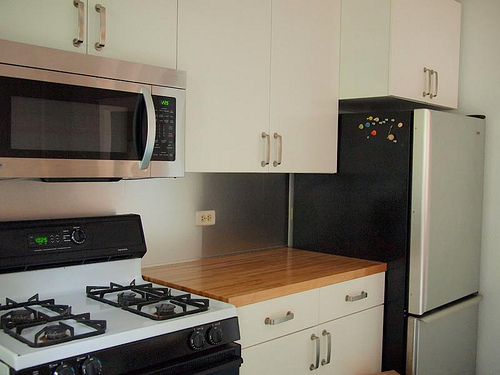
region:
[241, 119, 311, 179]
handles on a kitchen cabinet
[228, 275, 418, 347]
kitchen drawers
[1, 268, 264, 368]
gas stove top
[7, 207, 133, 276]
clock on a stove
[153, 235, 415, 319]
butcher block counter top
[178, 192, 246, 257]
electrical outlet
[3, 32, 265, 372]
microwave over a stove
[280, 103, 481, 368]
refrigerator with black sides and a stainless steel front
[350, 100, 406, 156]
magnets on the side of a refrigerator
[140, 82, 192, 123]
clock on microwave oven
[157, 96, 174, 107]
the numbers are lit up green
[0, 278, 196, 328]
the range is gas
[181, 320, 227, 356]
the knobs are black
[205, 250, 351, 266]
the counter is wooden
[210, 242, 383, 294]
the counter is brown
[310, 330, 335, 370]
the handles are metal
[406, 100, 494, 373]
the fridge is stainless steal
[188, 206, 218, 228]
the socket is on the wall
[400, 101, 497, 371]
the fridge is huge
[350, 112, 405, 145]
the magnets are on the fridge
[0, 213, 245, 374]
a black and white stove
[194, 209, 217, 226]
an electrical wall outlet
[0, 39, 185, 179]
a black and silver microwave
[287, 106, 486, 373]
a black and silver refrigerator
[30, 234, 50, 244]
a clock on a stove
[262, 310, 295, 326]
silver handle on drawer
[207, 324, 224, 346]
black knob on stove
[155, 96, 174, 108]
clock on a microwave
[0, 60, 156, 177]
silver door of microwave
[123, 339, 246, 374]
black door of stove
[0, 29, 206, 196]
microwave over the stove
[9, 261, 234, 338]
four burners on the stove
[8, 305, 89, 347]
the stove is gas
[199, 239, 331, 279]
counter top is wood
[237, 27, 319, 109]
cabinets are white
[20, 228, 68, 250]
clock on the stove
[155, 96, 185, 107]
clock on the microwave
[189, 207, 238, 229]
power outlet on the wall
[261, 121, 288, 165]
silver handles on the cabinets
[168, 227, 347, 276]
counter top is empty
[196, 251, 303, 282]
new brown wood counter top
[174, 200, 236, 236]
white electrical outlet on the wall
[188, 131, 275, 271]
cupboard lines cast on the surface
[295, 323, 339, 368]
silver doors on cabinet front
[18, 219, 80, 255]
green light on stove top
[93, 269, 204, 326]
black burners on top of stove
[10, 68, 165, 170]
clear door on microwave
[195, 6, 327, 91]
white color on cabinets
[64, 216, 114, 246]
black and silver knob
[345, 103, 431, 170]
large collection of magnets on fridge